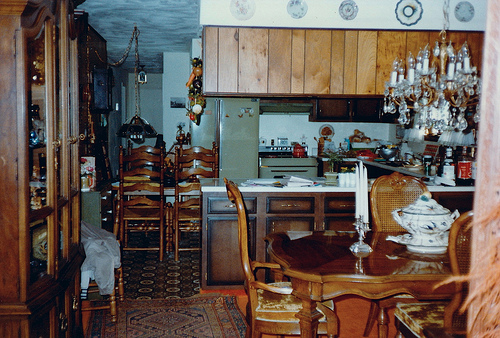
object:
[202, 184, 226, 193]
counter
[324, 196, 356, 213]
cabinets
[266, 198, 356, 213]
drawers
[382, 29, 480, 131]
chandelier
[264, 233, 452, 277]
table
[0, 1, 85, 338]
cabinet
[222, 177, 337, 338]
chair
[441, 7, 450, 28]
chain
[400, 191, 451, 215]
tureen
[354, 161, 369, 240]
candles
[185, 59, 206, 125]
fruit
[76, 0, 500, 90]
wall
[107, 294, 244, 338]
rug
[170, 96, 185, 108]
picture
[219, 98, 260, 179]
refigerator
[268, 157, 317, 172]
stove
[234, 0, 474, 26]
dishes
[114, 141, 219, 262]
chairs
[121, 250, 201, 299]
floor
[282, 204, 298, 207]
handles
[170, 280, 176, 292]
pattern